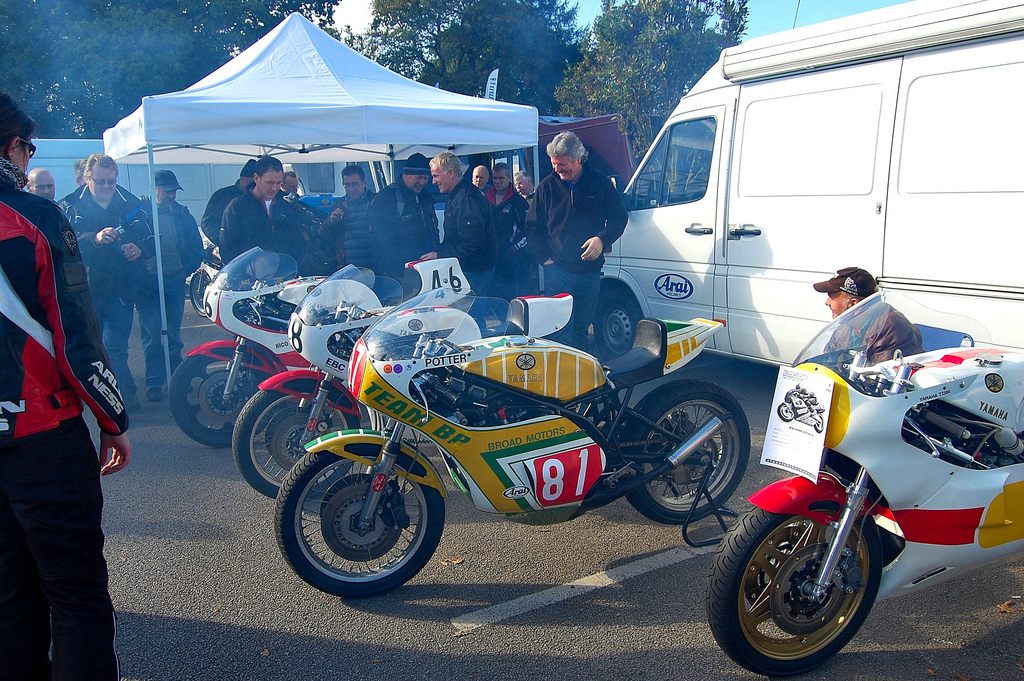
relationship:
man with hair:
[519, 127, 619, 290] [545, 119, 597, 167]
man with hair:
[415, 157, 534, 343] [430, 157, 463, 186]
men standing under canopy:
[158, 151, 528, 337] [101, 9, 540, 166]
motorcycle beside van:
[711, 342, 1021, 669] [587, 0, 1022, 385]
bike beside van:
[271, 284, 755, 599] [587, 0, 1022, 385]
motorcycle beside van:
[227, 281, 586, 510] [587, 0, 1022, 385]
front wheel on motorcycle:
[699, 489, 891, 681] [701, 342, 1024, 679]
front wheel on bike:
[270, 446, 452, 598] [272, 309, 748, 599]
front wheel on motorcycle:
[225, 379, 375, 501] [231, 262, 574, 501]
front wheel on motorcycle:
[160, 353, 271, 453] [231, 262, 574, 501]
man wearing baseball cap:
[812, 266, 927, 368] [812, 265, 877, 297]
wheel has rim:
[698, 465, 893, 677] [749, 532, 847, 653]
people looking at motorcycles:
[33, 119, 626, 344] [178, 229, 1017, 677]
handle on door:
[679, 215, 716, 241] [604, 80, 736, 322]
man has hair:
[523, 128, 632, 354] [541, 126, 585, 159]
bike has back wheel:
[271, 282, 753, 607] [619, 370, 758, 533]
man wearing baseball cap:
[812, 266, 927, 368] [807, 268, 879, 299]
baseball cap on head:
[807, 268, 879, 299] [820, 264, 879, 310]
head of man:
[820, 264, 879, 310] [812, 266, 927, 368]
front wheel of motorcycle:
[705, 489, 896, 673] [701, 342, 1024, 679]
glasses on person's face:
[3, 132, 43, 161] [1, 117, 40, 174]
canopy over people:
[101, 9, 540, 166] [189, 137, 537, 274]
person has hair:
[211, 156, 302, 303] [239, 148, 292, 187]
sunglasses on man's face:
[90, 167, 132, 183] [76, 156, 133, 211]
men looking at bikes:
[202, 137, 624, 306] [197, 217, 679, 486]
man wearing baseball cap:
[812, 266, 927, 368] [817, 268, 884, 305]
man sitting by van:
[789, 247, 915, 375] [587, 0, 1022, 385]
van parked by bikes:
[587, 0, 1022, 385] [197, 217, 679, 486]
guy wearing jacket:
[1, 89, 136, 677] [0, 175, 134, 446]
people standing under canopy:
[0, 119, 633, 417] [96, 14, 550, 189]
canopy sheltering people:
[129, 53, 499, 140] [213, 154, 611, 261]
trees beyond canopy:
[29, 70, 120, 105] [141, 50, 513, 182]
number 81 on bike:
[522, 457, 594, 501] [284, 351, 645, 509]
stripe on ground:
[519, 603, 621, 638] [511, 580, 699, 676]